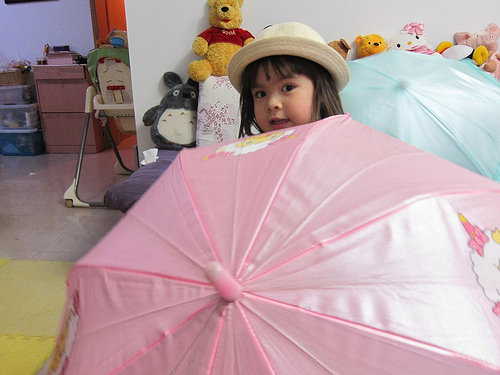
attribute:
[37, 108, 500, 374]
umbrella — pink, blue, opened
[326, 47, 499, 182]
umbrella — blue, opened, big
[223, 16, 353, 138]
girl — little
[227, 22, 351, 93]
hat — girl's, cream, white, beige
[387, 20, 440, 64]
hello kitty — stuffed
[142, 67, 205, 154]
bunny — strange looking, grey, white, stuffed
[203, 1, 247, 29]
head — winnie the pooh's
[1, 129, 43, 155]
container — storage, stacked, clear, plastic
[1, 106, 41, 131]
container — storage, stacked, clear, plastic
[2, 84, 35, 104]
container — storage, stacked, clear, plastic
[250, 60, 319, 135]
face — girl's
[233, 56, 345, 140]
hair — girl's, cut short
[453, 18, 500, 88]
animal — pig, stuffed, gray, white, winnie the pooh, big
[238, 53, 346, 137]
head — girl's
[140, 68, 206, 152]
animal — stuffed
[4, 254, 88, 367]
rug — yellow, gold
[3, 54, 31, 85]
box — toys, cardboard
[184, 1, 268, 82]
teddy bear — winnie the pooh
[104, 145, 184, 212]
covering — dark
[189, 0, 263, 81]
animal — stuffed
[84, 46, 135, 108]
seat — green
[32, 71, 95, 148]
nighstand — pink, smally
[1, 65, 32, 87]
basket — wicker, small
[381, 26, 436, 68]
animal — hello kitty, stuffed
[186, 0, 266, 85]
winnie the pooh — large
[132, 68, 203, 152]
tortorro — large, stuffed